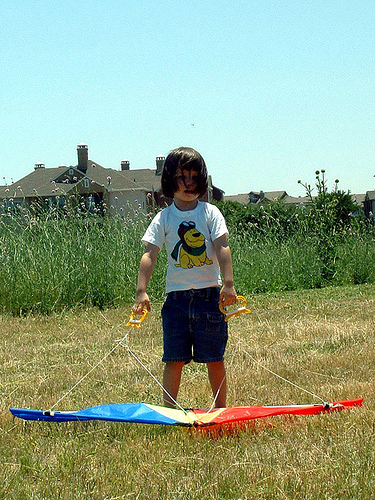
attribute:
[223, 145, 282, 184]
clouds — white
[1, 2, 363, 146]
sky — blue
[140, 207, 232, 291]
tee shirt — white, cotton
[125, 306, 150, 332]
handle — yellow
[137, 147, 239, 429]
girl — young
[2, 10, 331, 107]
sky — blue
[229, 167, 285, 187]
cloud — white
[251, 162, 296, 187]
cloud — white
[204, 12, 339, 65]
sky — blue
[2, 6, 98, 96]
sky — blue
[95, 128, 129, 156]
cloud — white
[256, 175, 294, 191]
cloud — white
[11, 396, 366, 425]
kite — colorful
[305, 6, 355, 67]
sky — blue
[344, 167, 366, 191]
cloud — white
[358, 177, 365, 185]
cloud — white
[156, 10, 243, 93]
sky — blue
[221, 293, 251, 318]
hook — yellow, kite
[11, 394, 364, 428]
kite — long, blue, red, yellow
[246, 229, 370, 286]
grass — tall, green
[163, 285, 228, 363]
shorts — jeans, blue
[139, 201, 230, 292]
shirt — white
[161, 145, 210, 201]
hair — black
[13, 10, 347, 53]
sky — blue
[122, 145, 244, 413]
girl — young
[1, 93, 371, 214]
clouds — white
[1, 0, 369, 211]
sky — blue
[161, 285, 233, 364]
shorts — dark blue, denim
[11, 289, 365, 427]
kite — blue, red, yellow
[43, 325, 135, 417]
rope — white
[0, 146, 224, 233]
house — brown, white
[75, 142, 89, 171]
chimney — stone